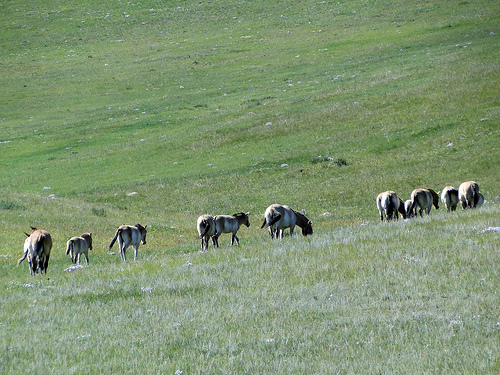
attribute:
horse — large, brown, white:
[211, 210, 252, 249]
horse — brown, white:
[105, 215, 152, 265]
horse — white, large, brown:
[387, 140, 458, 245]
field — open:
[170, 47, 462, 294]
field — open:
[1, 2, 498, 373]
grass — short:
[34, 237, 497, 366]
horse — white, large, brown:
[456, 181, 482, 208]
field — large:
[138, 52, 449, 166]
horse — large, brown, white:
[63, 221, 93, 271]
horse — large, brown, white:
[195, 213, 213, 248]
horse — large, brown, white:
[439, 184, 460, 211]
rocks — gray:
[169, 77, 263, 119]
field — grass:
[2, 24, 492, 356]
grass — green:
[1, 2, 496, 374]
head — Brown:
[242, 212, 252, 228]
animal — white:
[110, 223, 147, 263]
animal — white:
[65, 231, 93, 263]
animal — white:
[210, 210, 251, 247]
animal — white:
[456, 180, 480, 210]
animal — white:
[440, 185, 458, 210]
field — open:
[18, 201, 496, 367]